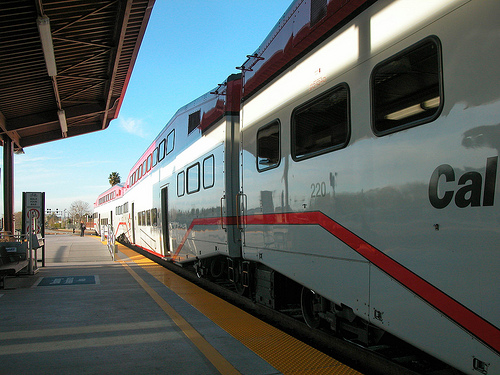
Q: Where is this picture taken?
A: A train station.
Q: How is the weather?
A: Sunny.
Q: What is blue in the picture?
A: The sky.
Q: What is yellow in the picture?
A: The painted platform lines.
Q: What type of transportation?
A: Train.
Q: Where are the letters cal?
A: On the train.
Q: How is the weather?
A: Sunny.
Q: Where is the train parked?
A: At the platform.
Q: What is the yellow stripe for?
A: Safety.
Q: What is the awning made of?
A: Wood.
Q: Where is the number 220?
A: On the side of the train.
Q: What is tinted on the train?
A: Windows.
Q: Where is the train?
A: At a platform.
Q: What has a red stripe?
A: Train.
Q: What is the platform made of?
A: Cement.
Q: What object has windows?
A: The train.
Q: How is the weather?
A: Clear.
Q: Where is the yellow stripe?
A: On the platform.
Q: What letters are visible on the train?
A: Cal.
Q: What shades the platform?
A: An overhead roof.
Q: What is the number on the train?
A: 220.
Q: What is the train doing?
A: Waiting for passengers.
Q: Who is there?
A: A woman.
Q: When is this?
A: Daytime.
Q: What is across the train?
A: Stripe.